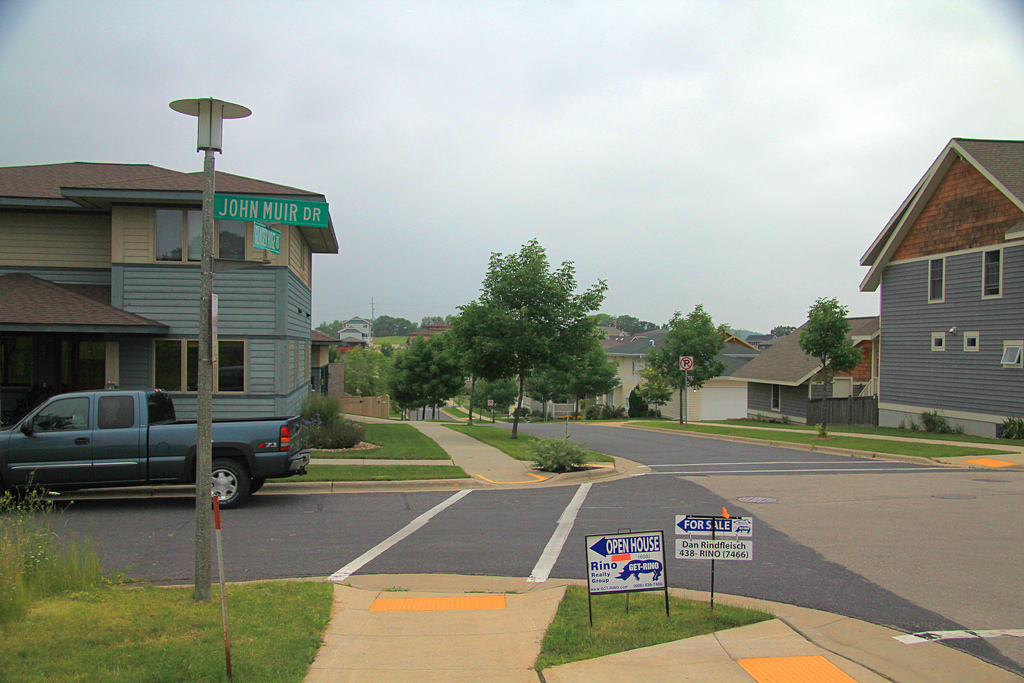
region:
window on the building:
[228, 329, 245, 388]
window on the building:
[185, 345, 195, 391]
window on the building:
[163, 341, 195, 390]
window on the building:
[223, 212, 244, 258]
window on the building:
[157, 209, 183, 266]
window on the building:
[962, 243, 1010, 292]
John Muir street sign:
[188, 165, 381, 236]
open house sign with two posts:
[571, 510, 723, 641]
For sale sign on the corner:
[669, 504, 783, 597]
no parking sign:
[671, 345, 710, 435]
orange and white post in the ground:
[200, 478, 259, 679]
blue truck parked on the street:
[11, 373, 356, 511]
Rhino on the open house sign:
[612, 552, 673, 591]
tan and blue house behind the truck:
[11, 161, 414, 479]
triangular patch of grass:
[523, 553, 770, 674]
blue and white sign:
[580, 514, 670, 616]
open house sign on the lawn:
[577, 514, 676, 628]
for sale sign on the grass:
[669, 481, 790, 598]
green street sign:
[201, 181, 339, 242]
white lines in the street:
[349, 449, 596, 605]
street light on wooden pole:
[169, 67, 252, 590]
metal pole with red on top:
[187, 476, 241, 670]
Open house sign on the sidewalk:
[582, 525, 671, 628]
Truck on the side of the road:
[9, 385, 619, 583]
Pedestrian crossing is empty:
[322, 476, 598, 591]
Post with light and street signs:
[166, 92, 338, 595]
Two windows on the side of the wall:
[925, 243, 1011, 307]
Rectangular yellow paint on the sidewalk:
[366, 591, 512, 611]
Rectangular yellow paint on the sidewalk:
[727, 648, 857, 680]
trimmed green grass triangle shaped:
[545, 584, 783, 667]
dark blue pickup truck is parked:
[0, 388, 314, 519]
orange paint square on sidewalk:
[296, 575, 894, 678]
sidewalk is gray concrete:
[299, 579, 894, 677]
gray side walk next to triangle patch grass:
[297, 581, 892, 679]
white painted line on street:
[6, 417, 1021, 678]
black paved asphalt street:
[0, 414, 1021, 678]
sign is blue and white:
[583, 527, 672, 630]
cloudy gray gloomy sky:
[0, 4, 1021, 337]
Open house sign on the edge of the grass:
[541, 523, 709, 637]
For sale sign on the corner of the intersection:
[654, 469, 778, 626]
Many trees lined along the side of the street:
[372, 204, 768, 449]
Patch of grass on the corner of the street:
[518, 547, 790, 637]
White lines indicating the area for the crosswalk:
[398, 424, 626, 593]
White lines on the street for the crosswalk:
[632, 411, 943, 506]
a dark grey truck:
[0, 379, 314, 529]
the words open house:
[600, 527, 662, 553]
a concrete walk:
[432, 405, 532, 478]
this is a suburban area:
[133, 66, 851, 661]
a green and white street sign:
[209, 177, 336, 235]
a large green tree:
[447, 240, 629, 455]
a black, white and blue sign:
[576, 527, 678, 620]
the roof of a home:
[2, 269, 159, 328]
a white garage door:
[696, 383, 751, 418]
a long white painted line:
[504, 478, 604, 578]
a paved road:
[497, 398, 1019, 673]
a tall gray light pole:
[168, 94, 257, 600]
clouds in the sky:
[287, 34, 853, 276]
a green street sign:
[215, 195, 336, 227]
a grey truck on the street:
[8, 393, 291, 488]